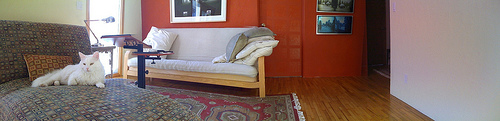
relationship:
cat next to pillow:
[28, 51, 108, 91] [23, 52, 76, 82]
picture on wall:
[316, 0, 355, 15] [141, 0, 370, 81]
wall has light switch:
[1, 1, 89, 33] [75, 1, 85, 14]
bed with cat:
[0, 17, 205, 119] [28, 51, 108, 91]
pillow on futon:
[134, 25, 178, 61] [121, 26, 267, 101]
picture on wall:
[315, 13, 353, 35] [141, 0, 370, 81]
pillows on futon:
[211, 25, 280, 68] [121, 26, 267, 101]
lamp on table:
[83, 14, 116, 49] [90, 43, 117, 80]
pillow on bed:
[23, 52, 76, 82] [0, 17, 205, 119]